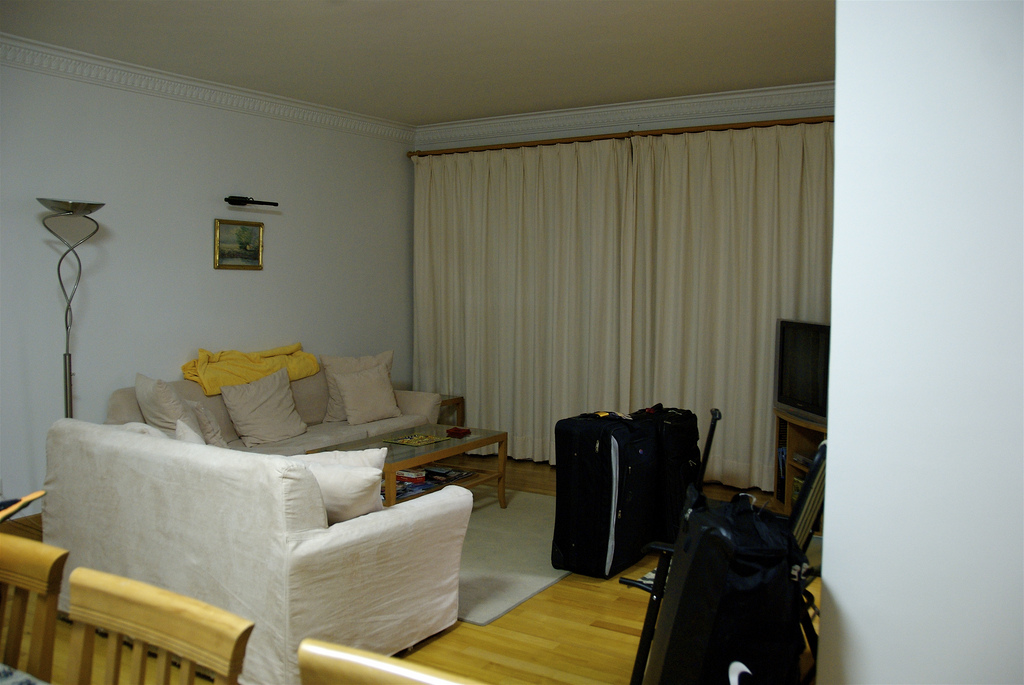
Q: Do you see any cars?
A: No, there are no cars.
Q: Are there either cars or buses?
A: No, there are no cars or buses.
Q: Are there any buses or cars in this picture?
A: No, there are no cars or buses.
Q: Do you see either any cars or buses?
A: No, there are no cars or buses.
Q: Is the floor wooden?
A: Yes, the floor is wooden.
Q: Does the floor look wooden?
A: Yes, the floor is wooden.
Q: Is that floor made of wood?
A: Yes, the floor is made of wood.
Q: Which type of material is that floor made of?
A: The floor is made of wood.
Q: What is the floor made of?
A: The floor is made of wood.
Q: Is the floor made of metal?
A: No, the floor is made of wood.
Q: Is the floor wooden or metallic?
A: The floor is wooden.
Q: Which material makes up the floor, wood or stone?
A: The floor is made of wood.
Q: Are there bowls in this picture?
A: No, there are no bowls.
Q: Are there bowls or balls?
A: No, there are no bowls or balls.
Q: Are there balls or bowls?
A: No, there are no bowls or balls.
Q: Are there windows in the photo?
A: Yes, there is a window.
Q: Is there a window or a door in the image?
A: Yes, there is a window.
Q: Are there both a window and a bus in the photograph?
A: No, there is a window but no buses.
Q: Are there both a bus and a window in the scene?
A: No, there is a window but no buses.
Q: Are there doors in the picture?
A: No, there are no doors.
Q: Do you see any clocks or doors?
A: No, there are no doors or clocks.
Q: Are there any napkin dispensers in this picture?
A: No, there are no napkin dispensers.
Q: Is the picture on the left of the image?
A: Yes, the picture is on the left of the image.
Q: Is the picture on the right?
A: No, the picture is on the left of the image.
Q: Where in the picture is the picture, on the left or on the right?
A: The picture is on the left of the image.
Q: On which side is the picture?
A: The picture is on the left of the image.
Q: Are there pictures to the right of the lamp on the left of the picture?
A: Yes, there is a picture to the right of the lamp.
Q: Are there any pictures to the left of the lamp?
A: No, the picture is to the right of the lamp.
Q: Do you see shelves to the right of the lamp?
A: No, there is a picture to the right of the lamp.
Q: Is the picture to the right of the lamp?
A: Yes, the picture is to the right of the lamp.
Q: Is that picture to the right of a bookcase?
A: No, the picture is to the right of the lamp.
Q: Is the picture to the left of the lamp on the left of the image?
A: No, the picture is to the right of the lamp.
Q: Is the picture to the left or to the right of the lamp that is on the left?
A: The picture is to the right of the lamp.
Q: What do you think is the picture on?
A: The picture is on the wall.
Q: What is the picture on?
A: The picture is on the wall.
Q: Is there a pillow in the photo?
A: Yes, there is a pillow.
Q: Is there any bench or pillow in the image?
A: Yes, there is a pillow.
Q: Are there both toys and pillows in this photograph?
A: No, there is a pillow but no toys.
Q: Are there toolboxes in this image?
A: No, there are no toolboxes.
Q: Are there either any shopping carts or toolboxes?
A: No, there are no toolboxes or shopping carts.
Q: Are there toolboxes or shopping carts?
A: No, there are no toolboxes or shopping carts.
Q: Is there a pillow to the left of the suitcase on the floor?
A: Yes, there is a pillow to the left of the suitcase.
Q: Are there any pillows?
A: Yes, there is a pillow.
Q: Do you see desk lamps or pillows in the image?
A: Yes, there is a pillow.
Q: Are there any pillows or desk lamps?
A: Yes, there is a pillow.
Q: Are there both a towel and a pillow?
A: No, there is a pillow but no towels.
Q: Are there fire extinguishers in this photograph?
A: No, there are no fire extinguishers.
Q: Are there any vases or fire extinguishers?
A: No, there are no fire extinguishers or vases.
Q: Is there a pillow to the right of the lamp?
A: Yes, there is a pillow to the right of the lamp.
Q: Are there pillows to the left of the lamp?
A: No, the pillow is to the right of the lamp.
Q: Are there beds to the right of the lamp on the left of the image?
A: No, there is a pillow to the right of the lamp.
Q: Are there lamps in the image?
A: Yes, there is a lamp.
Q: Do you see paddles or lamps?
A: Yes, there is a lamp.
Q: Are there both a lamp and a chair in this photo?
A: Yes, there are both a lamp and a chair.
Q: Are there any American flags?
A: No, there are no American flags.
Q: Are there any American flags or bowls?
A: No, there are no American flags or bowls.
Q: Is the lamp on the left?
A: Yes, the lamp is on the left of the image.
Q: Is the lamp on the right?
A: No, the lamp is on the left of the image.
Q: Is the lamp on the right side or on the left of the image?
A: The lamp is on the left of the image.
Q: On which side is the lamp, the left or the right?
A: The lamp is on the left of the image.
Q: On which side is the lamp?
A: The lamp is on the left of the image.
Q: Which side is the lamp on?
A: The lamp is on the left of the image.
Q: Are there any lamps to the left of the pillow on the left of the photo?
A: Yes, there is a lamp to the left of the pillow.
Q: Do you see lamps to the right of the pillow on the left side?
A: No, the lamp is to the left of the pillow.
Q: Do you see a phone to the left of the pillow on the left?
A: No, there is a lamp to the left of the pillow.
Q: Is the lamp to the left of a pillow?
A: Yes, the lamp is to the left of a pillow.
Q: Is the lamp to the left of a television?
A: No, the lamp is to the left of a pillow.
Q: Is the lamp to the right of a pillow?
A: No, the lamp is to the left of a pillow.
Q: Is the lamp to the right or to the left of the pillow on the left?
A: The lamp is to the left of the pillow.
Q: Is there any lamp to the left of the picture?
A: Yes, there is a lamp to the left of the picture.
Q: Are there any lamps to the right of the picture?
A: No, the lamp is to the left of the picture.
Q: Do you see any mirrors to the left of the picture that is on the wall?
A: No, there is a lamp to the left of the picture.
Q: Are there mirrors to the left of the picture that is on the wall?
A: No, there is a lamp to the left of the picture.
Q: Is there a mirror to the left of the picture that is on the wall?
A: No, there is a lamp to the left of the picture.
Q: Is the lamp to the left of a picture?
A: Yes, the lamp is to the left of a picture.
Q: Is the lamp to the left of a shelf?
A: No, the lamp is to the left of a picture.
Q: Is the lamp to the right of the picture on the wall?
A: No, the lamp is to the left of the picture.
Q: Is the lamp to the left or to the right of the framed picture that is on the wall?
A: The lamp is to the left of the picture.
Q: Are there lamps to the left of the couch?
A: Yes, there is a lamp to the left of the couch.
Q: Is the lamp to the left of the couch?
A: Yes, the lamp is to the left of the couch.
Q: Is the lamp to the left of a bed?
A: No, the lamp is to the left of the couch.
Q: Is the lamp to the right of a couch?
A: No, the lamp is to the left of a couch.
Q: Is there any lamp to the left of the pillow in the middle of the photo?
A: Yes, there is a lamp to the left of the pillow.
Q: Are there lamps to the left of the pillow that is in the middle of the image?
A: Yes, there is a lamp to the left of the pillow.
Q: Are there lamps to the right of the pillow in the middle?
A: No, the lamp is to the left of the pillow.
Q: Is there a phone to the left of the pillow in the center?
A: No, there is a lamp to the left of the pillow.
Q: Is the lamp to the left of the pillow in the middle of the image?
A: Yes, the lamp is to the left of the pillow.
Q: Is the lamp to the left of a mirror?
A: No, the lamp is to the left of the pillow.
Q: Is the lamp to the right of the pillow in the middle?
A: No, the lamp is to the left of the pillow.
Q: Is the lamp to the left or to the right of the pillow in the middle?
A: The lamp is to the left of the pillow.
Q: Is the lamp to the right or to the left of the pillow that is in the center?
A: The lamp is to the left of the pillow.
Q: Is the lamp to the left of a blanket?
A: Yes, the lamp is to the left of a blanket.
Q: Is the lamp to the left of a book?
A: No, the lamp is to the left of a blanket.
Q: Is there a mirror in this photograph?
A: No, there are no mirrors.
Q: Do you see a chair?
A: Yes, there is a chair.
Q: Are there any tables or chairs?
A: Yes, there is a chair.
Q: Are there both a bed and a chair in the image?
A: No, there is a chair but no beds.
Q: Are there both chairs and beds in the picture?
A: No, there is a chair but no beds.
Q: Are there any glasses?
A: No, there are no glasses.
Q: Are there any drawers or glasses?
A: No, there are no glasses or drawers.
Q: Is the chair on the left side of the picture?
A: Yes, the chair is on the left of the image.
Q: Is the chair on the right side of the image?
A: No, the chair is on the left of the image.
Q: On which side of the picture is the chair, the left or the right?
A: The chair is on the left of the image.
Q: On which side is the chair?
A: The chair is on the left of the image.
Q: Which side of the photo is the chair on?
A: The chair is on the left of the image.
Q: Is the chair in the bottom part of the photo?
A: Yes, the chair is in the bottom of the image.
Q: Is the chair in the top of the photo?
A: No, the chair is in the bottom of the image.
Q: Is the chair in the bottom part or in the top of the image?
A: The chair is in the bottom of the image.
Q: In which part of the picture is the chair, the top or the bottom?
A: The chair is in the bottom of the image.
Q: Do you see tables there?
A: Yes, there is a table.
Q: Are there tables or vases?
A: Yes, there is a table.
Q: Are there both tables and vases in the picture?
A: No, there is a table but no vases.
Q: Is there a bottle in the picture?
A: No, there are no bottles.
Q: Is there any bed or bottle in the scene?
A: No, there are no bottles or beds.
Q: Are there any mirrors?
A: No, there are no mirrors.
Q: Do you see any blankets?
A: Yes, there is a blanket.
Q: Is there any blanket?
A: Yes, there is a blanket.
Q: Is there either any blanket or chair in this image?
A: Yes, there is a blanket.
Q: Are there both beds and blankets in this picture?
A: No, there is a blanket but no beds.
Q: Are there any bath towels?
A: No, there are no bath towels.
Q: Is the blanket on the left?
A: Yes, the blanket is on the left of the image.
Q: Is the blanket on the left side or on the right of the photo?
A: The blanket is on the left of the image.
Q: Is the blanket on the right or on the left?
A: The blanket is on the left of the image.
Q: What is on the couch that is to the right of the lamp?
A: The blanket is on the couch.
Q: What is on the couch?
A: The blanket is on the couch.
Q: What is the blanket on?
A: The blanket is on the couch.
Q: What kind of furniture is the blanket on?
A: The blanket is on the couch.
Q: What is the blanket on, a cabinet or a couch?
A: The blanket is on a couch.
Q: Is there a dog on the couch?
A: No, there is a blanket on the couch.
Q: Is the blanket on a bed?
A: No, the blanket is on the couch.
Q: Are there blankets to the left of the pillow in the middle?
A: Yes, there is a blanket to the left of the pillow.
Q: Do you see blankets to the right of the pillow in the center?
A: No, the blanket is to the left of the pillow.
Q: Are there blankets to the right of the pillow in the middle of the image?
A: No, the blanket is to the left of the pillow.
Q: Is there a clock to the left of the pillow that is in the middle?
A: No, there is a blanket to the left of the pillow.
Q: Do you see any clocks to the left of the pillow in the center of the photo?
A: No, there is a blanket to the left of the pillow.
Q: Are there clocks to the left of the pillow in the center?
A: No, there is a blanket to the left of the pillow.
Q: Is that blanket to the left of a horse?
A: No, the blanket is to the left of the pillow.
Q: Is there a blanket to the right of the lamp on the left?
A: Yes, there is a blanket to the right of the lamp.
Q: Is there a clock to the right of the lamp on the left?
A: No, there is a blanket to the right of the lamp.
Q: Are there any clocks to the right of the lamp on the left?
A: No, there is a blanket to the right of the lamp.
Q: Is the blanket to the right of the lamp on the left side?
A: Yes, the blanket is to the right of the lamp.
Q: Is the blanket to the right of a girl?
A: No, the blanket is to the right of the lamp.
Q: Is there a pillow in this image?
A: Yes, there is a pillow.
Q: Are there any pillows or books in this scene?
A: Yes, there is a pillow.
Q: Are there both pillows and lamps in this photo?
A: Yes, there are both a pillow and a lamp.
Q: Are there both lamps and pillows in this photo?
A: Yes, there are both a pillow and a lamp.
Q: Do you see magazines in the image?
A: No, there are no magazines.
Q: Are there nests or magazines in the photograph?
A: No, there are no magazines or nests.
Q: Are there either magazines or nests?
A: No, there are no magazines or nests.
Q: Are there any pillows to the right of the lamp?
A: Yes, there is a pillow to the right of the lamp.